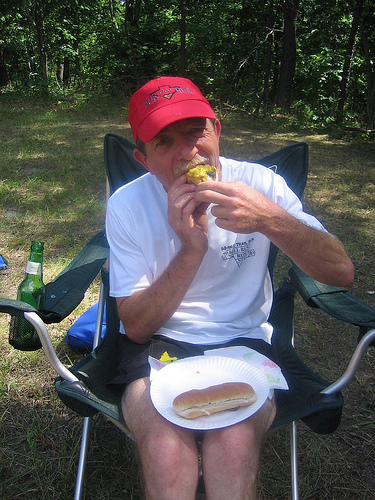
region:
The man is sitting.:
[77, 66, 359, 498]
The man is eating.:
[84, 48, 357, 499]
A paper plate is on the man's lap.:
[138, 341, 282, 438]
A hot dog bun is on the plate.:
[164, 376, 260, 429]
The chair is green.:
[35, 113, 374, 499]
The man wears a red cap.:
[118, 65, 233, 150]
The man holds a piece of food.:
[161, 154, 233, 224]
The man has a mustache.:
[165, 150, 214, 180]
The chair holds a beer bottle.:
[2, 231, 58, 357]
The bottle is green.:
[2, 236, 59, 360]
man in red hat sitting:
[108, 67, 288, 357]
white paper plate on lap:
[152, 345, 273, 432]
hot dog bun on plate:
[168, 380, 255, 421]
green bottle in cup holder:
[14, 233, 52, 346]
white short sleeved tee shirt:
[116, 148, 309, 342]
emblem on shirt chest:
[218, 231, 266, 272]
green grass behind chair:
[40, 131, 113, 216]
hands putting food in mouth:
[180, 156, 224, 195]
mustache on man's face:
[171, 152, 212, 175]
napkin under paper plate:
[221, 347, 282, 374]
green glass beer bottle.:
[22, 234, 47, 299]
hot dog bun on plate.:
[182, 377, 250, 411]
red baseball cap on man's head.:
[137, 73, 202, 122]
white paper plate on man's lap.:
[168, 364, 226, 380]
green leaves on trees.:
[83, 25, 165, 59]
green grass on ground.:
[21, 402, 57, 479]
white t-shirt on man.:
[126, 198, 159, 255]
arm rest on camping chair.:
[319, 291, 360, 318]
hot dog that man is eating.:
[192, 165, 215, 181]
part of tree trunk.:
[281, 11, 293, 109]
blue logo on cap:
[137, 78, 195, 101]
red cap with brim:
[114, 63, 237, 174]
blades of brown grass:
[298, 444, 353, 483]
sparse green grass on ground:
[9, 144, 80, 214]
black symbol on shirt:
[203, 237, 279, 279]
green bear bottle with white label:
[10, 235, 61, 384]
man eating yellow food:
[172, 165, 255, 187]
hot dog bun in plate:
[175, 380, 283, 430]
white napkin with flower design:
[195, 329, 295, 428]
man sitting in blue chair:
[80, 72, 364, 487]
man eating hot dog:
[67, 95, 343, 343]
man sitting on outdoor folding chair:
[48, 100, 341, 466]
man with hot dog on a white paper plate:
[101, 332, 297, 456]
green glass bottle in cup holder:
[11, 218, 53, 386]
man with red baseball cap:
[112, 70, 234, 165]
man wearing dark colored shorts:
[98, 307, 289, 489]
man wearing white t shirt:
[87, 115, 178, 251]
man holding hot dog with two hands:
[138, 165, 307, 261]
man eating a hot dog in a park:
[19, 40, 340, 225]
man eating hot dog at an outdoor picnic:
[57, 39, 341, 341]